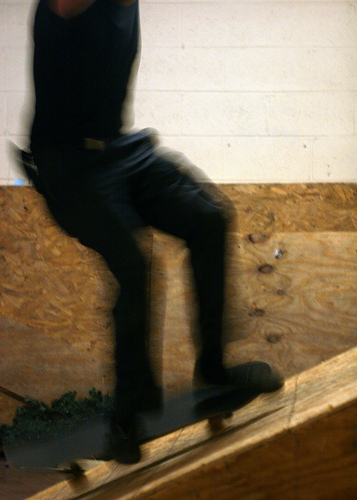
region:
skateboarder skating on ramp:
[19, 39, 304, 498]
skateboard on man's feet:
[85, 370, 331, 468]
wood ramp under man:
[61, 348, 345, 497]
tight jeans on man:
[52, 168, 276, 368]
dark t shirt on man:
[19, 8, 148, 143]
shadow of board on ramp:
[182, 412, 299, 494]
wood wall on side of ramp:
[2, 188, 350, 404]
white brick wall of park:
[3, 1, 353, 168]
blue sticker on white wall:
[2, 174, 29, 189]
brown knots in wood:
[257, 248, 279, 288]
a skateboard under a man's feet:
[4, 356, 274, 473]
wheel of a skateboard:
[65, 467, 89, 490]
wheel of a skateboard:
[205, 420, 227, 436]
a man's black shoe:
[105, 409, 144, 466]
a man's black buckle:
[81, 135, 107, 149]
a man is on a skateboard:
[7, 2, 283, 488]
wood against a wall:
[1, 184, 355, 439]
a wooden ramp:
[30, 344, 356, 498]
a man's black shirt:
[29, 0, 140, 141]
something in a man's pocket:
[12, 140, 44, 195]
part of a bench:
[315, 453, 318, 456]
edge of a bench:
[229, 429, 249, 461]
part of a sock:
[251, 394, 257, 405]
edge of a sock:
[220, 381, 227, 389]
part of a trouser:
[213, 315, 226, 341]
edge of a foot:
[204, 393, 209, 403]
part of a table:
[268, 325, 275, 358]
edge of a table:
[279, 446, 287, 457]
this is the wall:
[224, 36, 281, 92]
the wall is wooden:
[252, 126, 294, 170]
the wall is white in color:
[223, 24, 271, 63]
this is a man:
[36, 2, 232, 485]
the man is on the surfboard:
[28, 0, 258, 430]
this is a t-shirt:
[59, 52, 83, 73]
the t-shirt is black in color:
[66, 57, 85, 92]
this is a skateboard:
[37, 370, 294, 489]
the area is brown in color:
[289, 272, 313, 313]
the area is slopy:
[303, 380, 329, 435]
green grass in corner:
[6, 383, 108, 437]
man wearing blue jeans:
[31, 170, 245, 411]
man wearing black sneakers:
[182, 367, 300, 402]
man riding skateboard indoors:
[65, 382, 265, 482]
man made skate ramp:
[281, 346, 353, 480]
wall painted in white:
[199, 0, 299, 154]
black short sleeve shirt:
[23, 1, 135, 138]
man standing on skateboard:
[56, 385, 269, 434]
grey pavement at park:
[23, 437, 85, 460]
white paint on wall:
[205, 73, 355, 157]